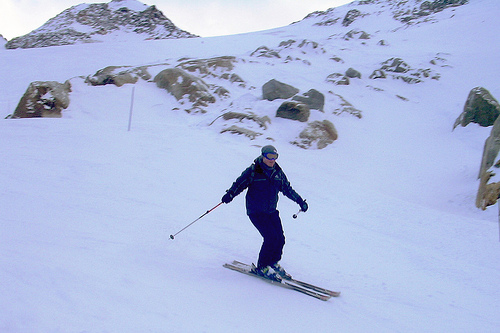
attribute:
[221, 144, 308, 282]
person — moving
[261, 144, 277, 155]
hat — blue, gray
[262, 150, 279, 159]
goggles — clear, blue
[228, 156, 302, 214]
coat — blue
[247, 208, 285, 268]
pants — blue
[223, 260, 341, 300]
skis — silver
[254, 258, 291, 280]
boots — blue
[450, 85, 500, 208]
rocks — large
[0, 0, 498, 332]
ground — rocky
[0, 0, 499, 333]
snow — white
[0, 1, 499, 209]
rocks — snowy, dirty, snow-covered, brown, dangerous, large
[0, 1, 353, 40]
sky — cloudy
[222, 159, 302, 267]
clothes — blue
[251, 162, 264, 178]
patch — black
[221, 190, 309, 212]
gloves — black